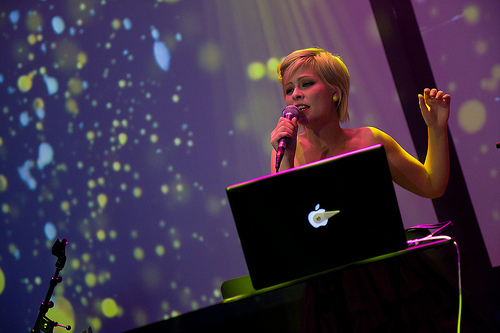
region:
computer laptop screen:
[224, 142, 409, 287]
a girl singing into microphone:
[267, 45, 454, 211]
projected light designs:
[1, 0, 498, 332]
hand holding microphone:
[269, 103, 301, 170]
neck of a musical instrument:
[33, 235, 73, 332]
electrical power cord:
[405, 227, 470, 332]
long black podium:
[87, 233, 498, 332]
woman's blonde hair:
[274, 47, 351, 127]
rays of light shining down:
[199, 1, 394, 204]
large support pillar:
[369, 0, 499, 332]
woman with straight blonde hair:
[275, 43, 355, 123]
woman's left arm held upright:
[413, 83, 458, 199]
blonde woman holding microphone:
[254, 49, 356, 175]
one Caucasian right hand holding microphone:
[264, 100, 302, 172]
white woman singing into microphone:
[259, 42, 461, 194]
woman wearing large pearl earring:
[277, 45, 349, 127]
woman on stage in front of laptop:
[224, 42, 460, 289]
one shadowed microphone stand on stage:
[36, 235, 76, 332]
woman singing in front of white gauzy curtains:
[223, 5, 371, 158]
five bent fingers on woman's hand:
[417, 85, 452, 129]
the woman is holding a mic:
[217, 35, 477, 233]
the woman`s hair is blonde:
[236, 30, 373, 115]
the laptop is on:
[220, 139, 427, 256]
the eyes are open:
[258, 72, 323, 99]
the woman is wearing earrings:
[321, 80, 351, 120]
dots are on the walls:
[20, 11, 220, 268]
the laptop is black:
[181, 140, 428, 285]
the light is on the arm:
[360, 115, 440, 185]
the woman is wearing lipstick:
[273, 94, 318, 120]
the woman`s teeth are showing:
[285, 95, 325, 126]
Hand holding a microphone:
[271, 104, 301, 176]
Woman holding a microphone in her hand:
[268, 46, 455, 201]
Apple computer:
[226, 143, 411, 298]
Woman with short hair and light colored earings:
[268, 46, 453, 200]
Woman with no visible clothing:
[268, 47, 453, 200]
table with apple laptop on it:
[101, 142, 463, 332]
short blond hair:
[277, 48, 352, 125]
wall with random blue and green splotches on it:
[3, 0, 498, 330]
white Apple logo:
[306, 203, 329, 227]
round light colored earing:
[331, 93, 336, 101]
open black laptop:
[198, 138, 423, 293]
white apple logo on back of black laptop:
[297, 192, 349, 232]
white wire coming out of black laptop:
[398, 226, 468, 331]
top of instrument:
[15, 225, 74, 331]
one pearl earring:
[326, 91, 340, 106]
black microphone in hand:
[267, 97, 311, 177]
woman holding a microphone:
[197, 38, 477, 302]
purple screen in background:
[3, 3, 453, 332]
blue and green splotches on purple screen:
[5, 10, 184, 235]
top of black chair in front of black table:
[217, 263, 262, 305]